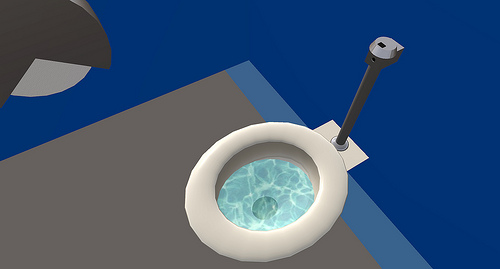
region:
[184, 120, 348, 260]
white seat of toilet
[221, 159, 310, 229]
water in toilet bowl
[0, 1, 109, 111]
toilet paper in dispenser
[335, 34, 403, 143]
flush sensor on post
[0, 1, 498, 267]
blue walls of bathroom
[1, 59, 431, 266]
gray floor of bathroom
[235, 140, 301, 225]
blue water in toilet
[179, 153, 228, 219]
edge of white toilet seat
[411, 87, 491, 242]
a dark blue floor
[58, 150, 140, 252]
gray paint on floor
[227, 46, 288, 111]
a light blue line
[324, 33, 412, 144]
a gray pipe on toilet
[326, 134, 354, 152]
a round silver ring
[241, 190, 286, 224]
a hole inside toilet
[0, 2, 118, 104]
a toilet paper container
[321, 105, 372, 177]
a white square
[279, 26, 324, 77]
Empty blue area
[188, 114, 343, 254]
Computer graphic image of toilet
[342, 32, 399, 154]
Toilet pipe extending from fixture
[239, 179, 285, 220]
Blue and white toilet water with drain opening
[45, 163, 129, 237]
Portion of blank gray area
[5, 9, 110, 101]
Large toilet paper dispenser on wall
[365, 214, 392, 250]
Blank light blue area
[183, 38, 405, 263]
CGI image of toilet and attached pipe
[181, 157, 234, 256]
Edge of toilet seat lid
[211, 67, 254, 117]
Gray and light blue colors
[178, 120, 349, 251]
animated view of a toilet bowl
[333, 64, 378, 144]
animated view of a pipe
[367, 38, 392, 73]
animated view of a flushing sensor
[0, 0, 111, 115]
animated view of a tissue dispenser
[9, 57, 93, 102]
animated view of a toilet paper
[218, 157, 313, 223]
animated view of water in the bowl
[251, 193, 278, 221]
animated view of a drain hole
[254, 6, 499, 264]
animated view of a bathroom wall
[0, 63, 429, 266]
animated view of a bathroom floor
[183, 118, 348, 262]
animated view of a toilet seat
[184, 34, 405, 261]
graphic of a toilet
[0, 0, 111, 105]
graphic of a toilet paper holder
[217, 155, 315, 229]
graphic of water in a toilet tank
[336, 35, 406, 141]
a shiny metal pole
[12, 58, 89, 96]
white toilet paper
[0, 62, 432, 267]
floor in a bathroom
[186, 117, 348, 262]
white toilet seat cover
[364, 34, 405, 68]
electronic flush sensor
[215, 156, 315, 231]
blue shimmering water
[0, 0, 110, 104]
plastic toilet paper holder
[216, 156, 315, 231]
blue water inside toilet bowl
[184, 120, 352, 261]
smooth white toilet seat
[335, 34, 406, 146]
metal pipe attached to toilet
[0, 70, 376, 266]
gray floor under toilet